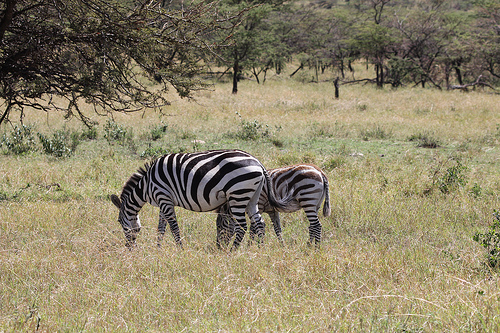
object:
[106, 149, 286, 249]
zebras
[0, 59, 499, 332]
grass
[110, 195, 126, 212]
ears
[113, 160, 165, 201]
mane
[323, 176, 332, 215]
tail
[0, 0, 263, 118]
tree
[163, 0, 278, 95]
trees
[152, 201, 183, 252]
legs